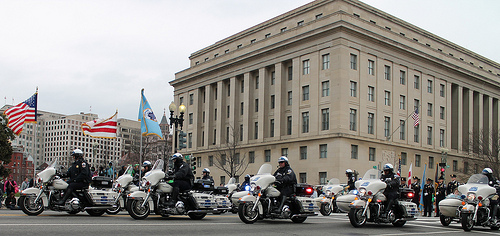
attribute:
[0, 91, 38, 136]
flag — white, red, waving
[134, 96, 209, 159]
flag — waving, blue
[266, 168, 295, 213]
outfit — dark colored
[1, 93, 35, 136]
flag — American